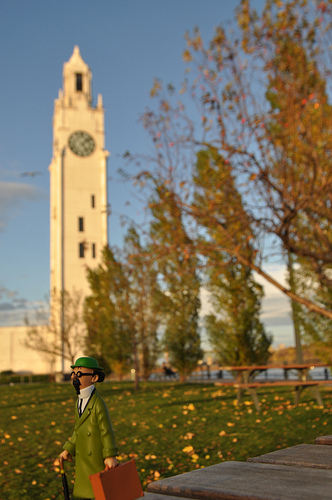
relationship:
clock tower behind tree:
[0, 45, 123, 373] [84, 250, 135, 378]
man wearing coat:
[31, 361, 133, 493] [63, 393, 108, 497]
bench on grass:
[203, 360, 328, 407] [6, 365, 307, 497]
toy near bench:
[56, 362, 124, 473] [203, 360, 328, 407]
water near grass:
[127, 355, 322, 380] [6, 365, 307, 497]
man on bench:
[58, 356, 119, 500] [203, 360, 328, 407]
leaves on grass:
[139, 425, 235, 483] [6, 365, 307, 497]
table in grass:
[215, 368, 318, 408] [6, 365, 307, 497]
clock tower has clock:
[0, 45, 123, 373] [70, 134, 102, 161]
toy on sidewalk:
[56, 362, 124, 473] [151, 452, 326, 495]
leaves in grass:
[139, 425, 235, 483] [6, 365, 307, 497]